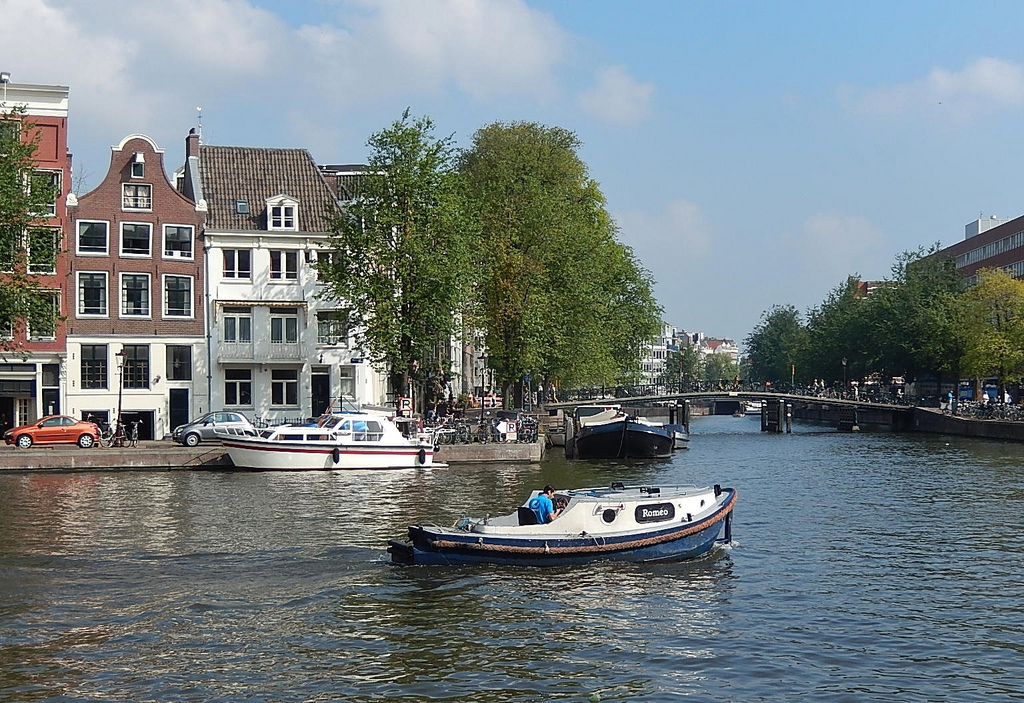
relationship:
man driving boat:
[526, 464, 572, 537] [388, 484, 736, 564]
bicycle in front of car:
[129, 418, 143, 447] [6, 414, 101, 449]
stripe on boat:
[221, 440, 437, 456] [220, 409, 436, 470]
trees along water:
[447, 118, 669, 409] [2, 409, 1023, 700]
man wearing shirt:
[529, 485, 561, 525] [527, 491, 554, 520]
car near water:
[11, 414, 103, 452] [2, 409, 1023, 700]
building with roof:
[170, 104, 398, 428] [199, 147, 361, 234]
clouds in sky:
[0, 0, 1022, 356] [0, 0, 1022, 358]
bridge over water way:
[545, 368, 969, 448] [668, 406, 1018, 569]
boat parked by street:
[220, 409, 436, 470] [2, 436, 231, 473]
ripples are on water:
[0, 414, 1022, 700] [2, 409, 1023, 700]